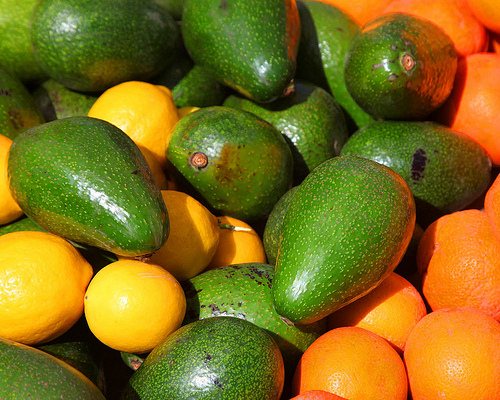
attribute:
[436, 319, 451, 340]
spotting — white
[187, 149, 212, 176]
stem — round, brown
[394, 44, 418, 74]
stem — round, brown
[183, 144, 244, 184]
bruise — brown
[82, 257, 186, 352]
fruit — red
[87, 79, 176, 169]
fruit — red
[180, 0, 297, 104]
fruit — green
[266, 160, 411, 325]
avocado — green.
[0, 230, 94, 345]
lemon — yellow.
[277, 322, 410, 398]
orange — bottom right, fully visible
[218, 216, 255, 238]
stem — broken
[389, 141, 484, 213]
spot — black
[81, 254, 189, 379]
lemon — yellow.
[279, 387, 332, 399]
top — bottom right.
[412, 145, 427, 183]
blemish — black, largest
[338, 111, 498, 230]
fruit — green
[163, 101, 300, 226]
avocado — green.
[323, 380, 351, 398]
orange — Barely visible top 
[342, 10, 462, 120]
fruit — green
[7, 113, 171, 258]
fruit — green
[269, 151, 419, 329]
fruit — green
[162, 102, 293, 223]
fruit — green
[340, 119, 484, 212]
fruit — green